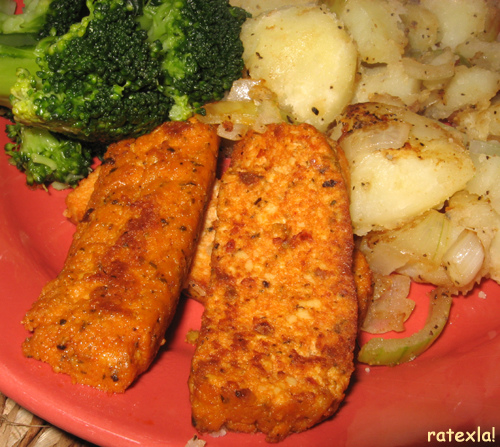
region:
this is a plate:
[127, 391, 159, 435]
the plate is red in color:
[0, 194, 39, 281]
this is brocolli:
[47, 21, 182, 96]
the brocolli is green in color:
[47, 27, 144, 108]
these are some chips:
[386, 83, 491, 259]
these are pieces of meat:
[120, 177, 308, 374]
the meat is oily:
[115, 197, 144, 284]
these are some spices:
[371, 251, 450, 376]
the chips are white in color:
[274, 25, 346, 70]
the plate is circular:
[36, 390, 165, 441]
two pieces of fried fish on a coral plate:
[18, 96, 360, 436]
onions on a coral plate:
[371, 278, 462, 366]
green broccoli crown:
[13, 7, 168, 130]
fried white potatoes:
[264, 6, 469, 113]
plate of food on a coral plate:
[0, 1, 498, 346]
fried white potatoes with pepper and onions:
[351, 101, 480, 175]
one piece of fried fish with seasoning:
[199, 123, 361, 430]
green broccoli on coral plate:
[9, 42, 85, 225]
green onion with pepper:
[378, 284, 458, 374]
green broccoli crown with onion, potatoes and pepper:
[146, 42, 277, 122]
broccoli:
[7, 7, 164, 124]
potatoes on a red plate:
[240, 7, 481, 113]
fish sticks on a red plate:
[107, 140, 334, 433]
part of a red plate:
[361, 370, 487, 417]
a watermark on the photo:
[421, 423, 496, 443]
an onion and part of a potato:
[370, 280, 445, 366]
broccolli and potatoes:
[165, 5, 312, 72]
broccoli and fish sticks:
[8, 6, 168, 392]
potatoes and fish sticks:
[241, 6, 357, 396]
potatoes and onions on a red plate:
[356, 187, 490, 419]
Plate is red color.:
[356, 319, 488, 430]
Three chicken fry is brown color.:
[50, 182, 380, 413]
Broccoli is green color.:
[32, 22, 138, 122]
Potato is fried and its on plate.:
[286, 18, 456, 150]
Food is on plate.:
[22, 42, 464, 372]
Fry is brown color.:
[75, 195, 347, 386]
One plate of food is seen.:
[13, 35, 443, 407]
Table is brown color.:
[5, 405, 75, 442]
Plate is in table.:
[6, 380, 89, 445]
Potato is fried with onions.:
[373, 252, 488, 369]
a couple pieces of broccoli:
[26, 10, 262, 120]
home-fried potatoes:
[257, 17, 498, 277]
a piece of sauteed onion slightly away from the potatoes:
[355, 271, 475, 378]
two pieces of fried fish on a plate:
[40, 133, 370, 435]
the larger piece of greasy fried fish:
[192, 133, 372, 425]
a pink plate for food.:
[8, 146, 490, 438]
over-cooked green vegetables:
[7, 10, 241, 175]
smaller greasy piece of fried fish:
[13, 138, 213, 379]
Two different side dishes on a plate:
[22, 12, 498, 285]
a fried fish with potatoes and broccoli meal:
[22, 18, 477, 383]